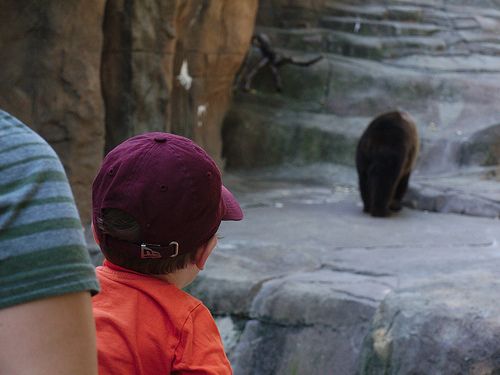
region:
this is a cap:
[141, 131, 209, 232]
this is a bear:
[335, 104, 435, 228]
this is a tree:
[37, 17, 211, 103]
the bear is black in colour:
[351, 109, 464, 232]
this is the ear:
[190, 230, 220, 272]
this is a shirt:
[118, 293, 220, 370]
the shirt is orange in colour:
[102, 283, 199, 372]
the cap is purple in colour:
[106, 159, 233, 216]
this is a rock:
[255, 220, 412, 301]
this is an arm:
[6, 196, 92, 373]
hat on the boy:
[95, 130, 228, 275]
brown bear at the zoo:
[290, 115, 444, 228]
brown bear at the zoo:
[340, 103, 475, 238]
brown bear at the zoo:
[337, 115, 417, 258]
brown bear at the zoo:
[350, 115, 437, 196]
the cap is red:
[98, 135, 240, 252]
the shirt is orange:
[91, 266, 219, 374]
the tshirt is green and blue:
[2, 119, 97, 290]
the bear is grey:
[355, 100, 437, 217]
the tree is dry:
[133, 7, 251, 164]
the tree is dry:
[3, 6, 125, 223]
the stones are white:
[211, 267, 496, 367]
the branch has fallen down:
[251, 37, 322, 96]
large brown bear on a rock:
[345, 99, 425, 219]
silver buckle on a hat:
[166, 237, 183, 264]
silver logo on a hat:
[135, 241, 160, 264]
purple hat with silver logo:
[76, 124, 248, 280]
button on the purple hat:
[149, 130, 171, 146]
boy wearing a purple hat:
[81, 119, 261, 374]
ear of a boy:
[193, 232, 222, 276]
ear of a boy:
[87, 217, 99, 251]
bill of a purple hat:
[216, 174, 243, 231]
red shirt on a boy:
[86, 262, 236, 374]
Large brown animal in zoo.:
[353, 107, 415, 219]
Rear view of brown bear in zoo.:
[352, 109, 417, 216]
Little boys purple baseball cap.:
[89, 131, 244, 261]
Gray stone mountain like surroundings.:
[322, 23, 479, 98]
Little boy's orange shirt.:
[100, 265, 231, 372]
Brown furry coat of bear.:
[354, 108, 415, 218]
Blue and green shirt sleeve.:
[2, 113, 105, 304]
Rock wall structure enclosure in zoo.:
[107, 0, 267, 122]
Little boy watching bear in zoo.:
[94, 131, 249, 373]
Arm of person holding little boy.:
[4, 288, 96, 373]